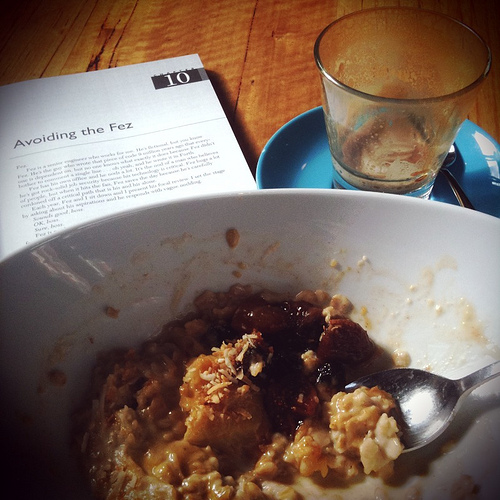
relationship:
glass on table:
[305, 3, 492, 177] [3, 3, 498, 221]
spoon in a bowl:
[387, 348, 497, 468] [8, 184, 496, 499]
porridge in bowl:
[77, 287, 411, 499] [8, 184, 496, 499]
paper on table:
[1, 54, 255, 262] [3, 3, 498, 221]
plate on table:
[252, 100, 500, 216] [3, 3, 498, 221]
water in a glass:
[331, 122, 445, 193] [305, 3, 492, 177]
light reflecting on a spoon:
[387, 388, 433, 425] [387, 348, 497, 468]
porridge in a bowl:
[77, 287, 411, 499] [8, 184, 496, 499]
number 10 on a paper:
[158, 70, 192, 89] [1, 54, 255, 262]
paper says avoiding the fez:
[1, 54, 255, 262] [12, 113, 135, 157]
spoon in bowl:
[387, 348, 497, 468] [8, 184, 496, 499]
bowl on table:
[8, 184, 496, 499] [3, 3, 498, 221]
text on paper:
[16, 128, 220, 238] [1, 54, 255, 262]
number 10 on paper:
[158, 70, 192, 89] [1, 54, 255, 262]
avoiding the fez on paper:
[12, 113, 135, 157] [1, 54, 255, 262]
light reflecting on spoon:
[387, 388, 433, 425] [387, 348, 497, 468]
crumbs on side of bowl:
[32, 215, 248, 393] [8, 184, 496, 499]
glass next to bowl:
[305, 3, 492, 177] [8, 184, 496, 499]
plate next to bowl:
[252, 100, 500, 216] [8, 184, 496, 499]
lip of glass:
[313, 6, 488, 105] [305, 3, 492, 177]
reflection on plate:
[471, 126, 500, 185] [252, 100, 500, 216]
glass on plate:
[305, 3, 492, 177] [252, 100, 500, 216]